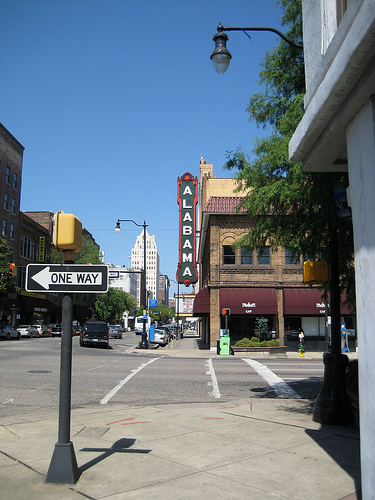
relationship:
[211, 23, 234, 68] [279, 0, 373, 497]
light fixed in wall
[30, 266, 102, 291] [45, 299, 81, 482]
arrow on pole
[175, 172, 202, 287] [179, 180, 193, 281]
board describes business name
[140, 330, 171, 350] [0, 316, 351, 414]
vehicle in road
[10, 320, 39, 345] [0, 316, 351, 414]
vehicle in road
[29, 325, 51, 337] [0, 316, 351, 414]
vehicle in road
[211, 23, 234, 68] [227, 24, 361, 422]
light in a pole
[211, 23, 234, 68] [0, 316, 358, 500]
light standing in road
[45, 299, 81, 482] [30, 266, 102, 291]
pole has arrow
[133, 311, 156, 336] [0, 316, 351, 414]
bus moving in road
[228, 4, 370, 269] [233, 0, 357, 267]
tree has leave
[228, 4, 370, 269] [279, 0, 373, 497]
tree behind wall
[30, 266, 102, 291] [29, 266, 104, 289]
arrow has arrow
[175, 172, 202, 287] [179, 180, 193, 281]
board has business name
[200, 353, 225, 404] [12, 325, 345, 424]
line painted on asphalt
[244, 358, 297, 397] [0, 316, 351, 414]
line painted on road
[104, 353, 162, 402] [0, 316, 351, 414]
line painted on road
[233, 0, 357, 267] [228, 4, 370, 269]
leave from a tree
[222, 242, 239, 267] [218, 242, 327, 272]
window in a row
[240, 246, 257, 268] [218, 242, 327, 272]
window in a row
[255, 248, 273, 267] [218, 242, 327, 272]
window in a row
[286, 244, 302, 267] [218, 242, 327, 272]
window in a row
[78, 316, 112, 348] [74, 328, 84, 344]
car has light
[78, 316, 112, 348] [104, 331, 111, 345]
car has light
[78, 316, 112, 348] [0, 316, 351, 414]
car driving down road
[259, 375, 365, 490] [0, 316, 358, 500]
shadow on road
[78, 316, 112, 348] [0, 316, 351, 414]
car onto road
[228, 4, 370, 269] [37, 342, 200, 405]
tree near an intersection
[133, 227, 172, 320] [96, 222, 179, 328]
building in distance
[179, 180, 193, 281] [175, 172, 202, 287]
business name on board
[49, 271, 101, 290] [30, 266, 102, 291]
text on arrow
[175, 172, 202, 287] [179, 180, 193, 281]
board say alabama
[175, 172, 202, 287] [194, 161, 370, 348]
board on building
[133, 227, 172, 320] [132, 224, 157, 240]
building has top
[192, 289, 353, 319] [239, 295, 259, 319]
awning has text